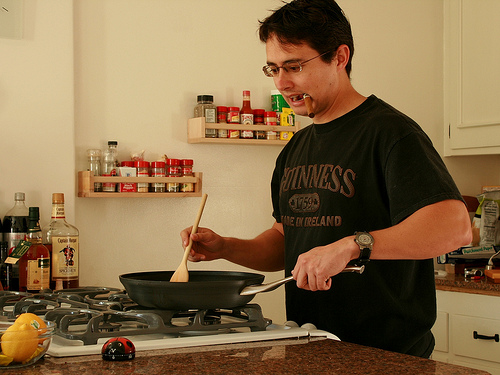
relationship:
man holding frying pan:
[178, 1, 478, 363] [115, 264, 371, 311]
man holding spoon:
[180, 0, 473, 359] [169, 193, 208, 282]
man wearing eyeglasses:
[178, 1, 478, 363] [256, 46, 326, 78]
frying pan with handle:
[132, 255, 359, 329] [238, 236, 364, 315]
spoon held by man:
[165, 183, 220, 284] [246, 15, 431, 322]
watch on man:
[351, 229, 376, 267] [251, 5, 451, 374]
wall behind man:
[1, 0, 499, 325] [238, 1, 485, 368]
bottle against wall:
[46, 194, 96, 294] [174, 83, 369, 188]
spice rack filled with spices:
[186, 118, 300, 152] [86, 140, 198, 190]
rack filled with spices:
[78, 170, 204, 197] [196, 91, 298, 138]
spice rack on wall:
[186, 118, 300, 152] [1, 0, 499, 325]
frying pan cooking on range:
[118, 265, 365, 311] [83, 293, 323, 344]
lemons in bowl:
[7, 317, 45, 365] [0, 308, 55, 369]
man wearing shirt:
[178, 1, 478, 363] [264, 93, 466, 358]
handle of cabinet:
[467, 329, 499, 347] [448, 312, 498, 366]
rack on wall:
[82, 151, 212, 209] [54, 43, 455, 272]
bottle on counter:
[3, 192, 30, 293] [0, 282, 6, 290]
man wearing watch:
[180, 0, 473, 359] [354, 229, 375, 266]